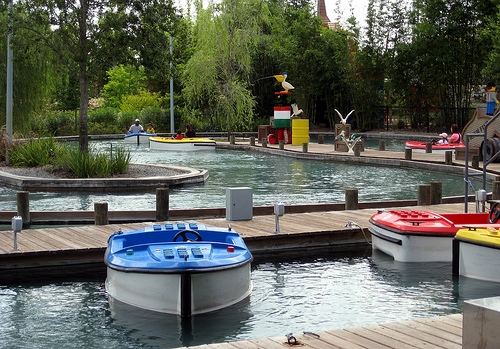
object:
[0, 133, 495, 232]
pond